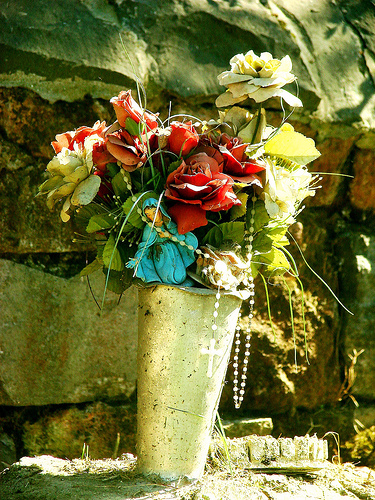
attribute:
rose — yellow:
[213, 45, 303, 118]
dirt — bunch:
[251, 432, 339, 478]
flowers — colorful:
[114, 123, 243, 246]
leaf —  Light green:
[85, 216, 113, 232]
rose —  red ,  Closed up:
[109, 88, 159, 136]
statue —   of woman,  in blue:
[122, 195, 199, 285]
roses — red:
[48, 94, 261, 233]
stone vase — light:
[136, 280, 240, 483]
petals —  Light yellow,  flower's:
[273, 132, 316, 153]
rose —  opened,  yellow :
[216, 43, 304, 103]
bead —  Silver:
[233, 329, 242, 341]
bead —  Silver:
[228, 356, 239, 361]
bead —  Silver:
[233, 371, 242, 379]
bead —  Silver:
[228, 383, 241, 397]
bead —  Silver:
[236, 402, 241, 411]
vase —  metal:
[132, 273, 248, 481]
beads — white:
[163, 229, 239, 263]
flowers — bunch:
[90, 80, 323, 284]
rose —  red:
[157, 151, 242, 234]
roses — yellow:
[175, 40, 289, 222]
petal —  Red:
[168, 203, 207, 234]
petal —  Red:
[218, 145, 242, 173]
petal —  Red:
[241, 160, 265, 174]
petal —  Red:
[177, 171, 210, 184]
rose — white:
[215, 49, 303, 106]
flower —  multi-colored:
[37, 150, 102, 223]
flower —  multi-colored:
[211, 47, 302, 107]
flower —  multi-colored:
[110, 88, 160, 133]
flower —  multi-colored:
[162, 154, 241, 229]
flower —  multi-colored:
[163, 117, 201, 155]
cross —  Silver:
[197, 337, 226, 379]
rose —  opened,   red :
[162, 152, 241, 236]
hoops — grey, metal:
[129, 141, 186, 194]